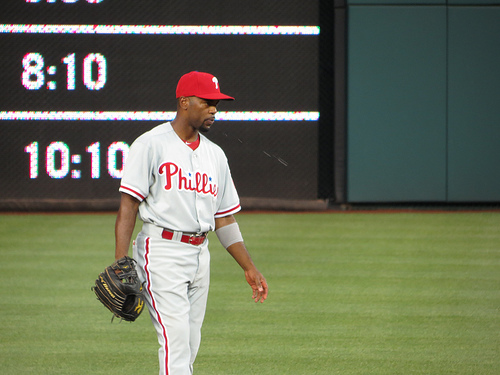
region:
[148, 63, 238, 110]
The player is wearing red cap.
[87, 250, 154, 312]
Player is holding a glove.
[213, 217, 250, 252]
Band around the elbow.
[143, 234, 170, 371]
A red stripe line on side of pants.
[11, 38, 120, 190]
digital clock on the wall.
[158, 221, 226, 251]
The belt is red.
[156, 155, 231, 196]
Name of the team in front of jersey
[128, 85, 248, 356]
the player is standing on the field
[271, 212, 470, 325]
The field is green.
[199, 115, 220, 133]
The player has facial hair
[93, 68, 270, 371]
Philadelphia "Phillies" baseball player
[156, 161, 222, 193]
Phillies written in red on white jersey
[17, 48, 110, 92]
time on the score board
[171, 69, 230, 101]
red cap on player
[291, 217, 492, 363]
grass cut in striped pattern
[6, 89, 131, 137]
white lights on the black scoreboard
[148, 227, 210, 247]
red belt on Phillies player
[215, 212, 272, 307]
left arm of player bandaged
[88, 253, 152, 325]
black glove in player right hand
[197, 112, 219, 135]
mustache and goatee on players face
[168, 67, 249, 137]
A man is wearing a red cap.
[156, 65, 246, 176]
A cap is covering a mans head.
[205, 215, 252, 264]
a arm band is on a mans arm.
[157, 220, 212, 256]
A man is wearing a red belt.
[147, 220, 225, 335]
A red belt is supporting a mans pants.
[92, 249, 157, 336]
A man is holding a catchers mit.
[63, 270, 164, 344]
A catchers mit is held by a man.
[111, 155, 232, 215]
A man wearing a red and white shirt.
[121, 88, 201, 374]
a man standing in a baseball field.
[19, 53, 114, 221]
Numbers are displayed on a score board.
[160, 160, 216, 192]
team name on a jersey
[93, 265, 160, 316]
a black leather baseball mitt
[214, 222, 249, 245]
a gray band on an arm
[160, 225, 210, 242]
red belt around a waist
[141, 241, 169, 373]
a red stripe on gray pants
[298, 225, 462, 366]
thick green grass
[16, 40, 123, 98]
white numbers on a black board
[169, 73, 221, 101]
a red cap on a head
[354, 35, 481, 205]
a blue wall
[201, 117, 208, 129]
a black beard on a face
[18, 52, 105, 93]
it is 8:10 in white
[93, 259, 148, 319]
the glove of the player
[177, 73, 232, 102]
a beautiful red cap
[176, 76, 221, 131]
the head of the player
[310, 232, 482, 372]
a lot of grass in the field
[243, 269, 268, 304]
the hand of the player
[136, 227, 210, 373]
the two legs of the baseball player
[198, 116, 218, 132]
the beard is black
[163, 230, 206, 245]
he is wearing a red belt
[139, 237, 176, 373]
a vertical red stripe